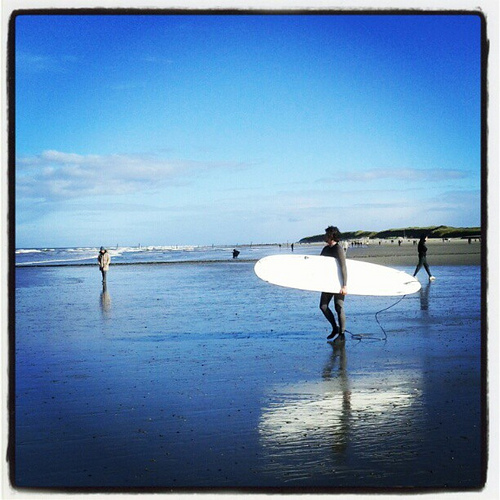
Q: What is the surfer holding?
A: A surfboard.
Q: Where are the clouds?
A: In the sky.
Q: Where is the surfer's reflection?
A: In the water.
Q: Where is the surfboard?
A: Under the surfer's arm.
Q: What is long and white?
A: The surfboard.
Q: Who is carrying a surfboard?
A: The surfer.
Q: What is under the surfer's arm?
A: A surfboard.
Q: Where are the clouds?
A: Above the water.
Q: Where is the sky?
A: Above the earth.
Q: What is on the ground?
A: A reflection.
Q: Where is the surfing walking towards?
A: The ocean.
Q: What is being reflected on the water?
A: A surfer.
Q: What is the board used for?
A: Surfing.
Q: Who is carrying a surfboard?
A: A board rider.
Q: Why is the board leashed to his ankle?
A: To keep it near when lost.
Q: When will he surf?
A: Very soon.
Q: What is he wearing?
A: A wet suit.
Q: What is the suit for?
A: Warmth and safety.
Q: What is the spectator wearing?
A: A warm coat.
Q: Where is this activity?
A: At the beach shore.